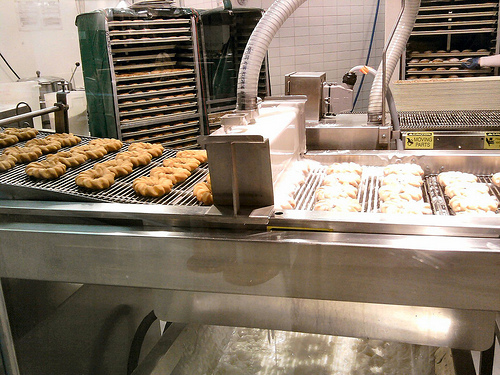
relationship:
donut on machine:
[132, 178, 172, 198] [0, 110, 474, 319]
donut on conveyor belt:
[132, 178, 172, 198] [25, 123, 481, 227]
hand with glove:
[450, 53, 480, 73] [459, 52, 480, 72]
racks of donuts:
[403, 46, 483, 78] [403, 56, 482, 60]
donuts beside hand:
[403, 56, 482, 60] [457, 52, 479, 73]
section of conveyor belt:
[209, 95, 312, 218] [7, 127, 474, 235]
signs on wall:
[13, 0, 61, 30] [6, 1, 95, 86]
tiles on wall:
[324, 22, 355, 42] [267, 5, 381, 107]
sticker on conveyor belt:
[403, 130, 435, 150] [390, 104, 484, 145]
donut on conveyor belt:
[132, 178, 172, 198] [7, 127, 474, 235]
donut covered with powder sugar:
[308, 194, 369, 216] [316, 197, 356, 210]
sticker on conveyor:
[403, 130, 435, 150] [391, 99, 484, 139]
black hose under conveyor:
[124, 307, 158, 373] [16, 172, 76, 194]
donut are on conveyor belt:
[308, 194, 369, 216] [292, 187, 320, 209]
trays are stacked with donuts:
[115, 73, 193, 116] [142, 162, 172, 192]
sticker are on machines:
[403, 130, 435, 150] [394, 105, 478, 139]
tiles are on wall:
[324, 22, 355, 42] [303, 10, 357, 64]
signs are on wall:
[13, 0, 61, 33] [38, 41, 68, 64]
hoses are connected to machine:
[237, 16, 282, 98] [286, 69, 360, 129]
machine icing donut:
[17, 110, 475, 320] [308, 194, 369, 216]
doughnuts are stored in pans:
[118, 64, 192, 93] [120, 114, 197, 129]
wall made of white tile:
[268, 25, 352, 70] [310, 42, 325, 56]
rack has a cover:
[108, 17, 195, 139] [79, 39, 108, 105]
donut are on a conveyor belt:
[132, 178, 172, 198] [6, 180, 79, 197]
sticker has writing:
[406, 131, 439, 150] [403, 132, 420, 144]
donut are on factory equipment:
[308, 194, 369, 216] [202, 102, 482, 328]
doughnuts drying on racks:
[118, 64, 192, 93] [124, 66, 196, 128]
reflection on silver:
[184, 238, 281, 289] [17, 222, 428, 309]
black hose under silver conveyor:
[129, 307, 156, 367] [0, 115, 483, 338]